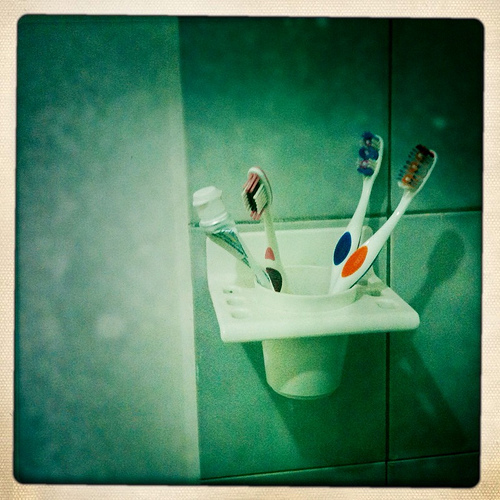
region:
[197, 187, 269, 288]
The tube of toothpaste.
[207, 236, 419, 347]
The toothbrush holder.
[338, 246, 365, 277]
The orange oval on the toothbrush.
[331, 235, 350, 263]
The blue oval on the toothbrush.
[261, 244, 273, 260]
The pink design on the toothbrush.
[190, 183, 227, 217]
The cap of the toothpaste.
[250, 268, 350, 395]
The cup the toothbrushes and toothpaste are in.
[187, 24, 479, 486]
The tile wall the toothbrush holder is mounted to.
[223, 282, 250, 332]
The holes on the left of the cup.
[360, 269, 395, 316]
The holes to the right of the cup.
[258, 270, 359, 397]
white plastic cup in toothbrush holder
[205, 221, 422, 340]
ceramic toothbrush holder on wall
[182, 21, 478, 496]
green tile on the wall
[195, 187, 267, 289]
a partial tube of toothpast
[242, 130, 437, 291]
three toothbrushes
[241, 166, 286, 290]
the toothbrush with pink and green bristles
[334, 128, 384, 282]
the toothbrush with blue handle and blue bristles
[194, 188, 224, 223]
white cap on toothpaste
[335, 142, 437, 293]
toothbrush with orange on handle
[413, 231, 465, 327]
shadow of a toothbrush on the tile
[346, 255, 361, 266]
orange color on toothbrush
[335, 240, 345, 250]
blue color on toothbrush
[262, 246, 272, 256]
pink color on toothbrush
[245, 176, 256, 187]
pink bristles on top toothbrush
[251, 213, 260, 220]
pink bristles on bottom toothbrush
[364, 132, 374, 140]
blue bristles on top toothbrush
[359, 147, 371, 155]
blue bristles on middle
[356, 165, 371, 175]
blue bristles on bottom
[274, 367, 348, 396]
white cup in cup holder on wall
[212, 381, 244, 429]
teal green tile on wall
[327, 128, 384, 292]
blue and white toothbrush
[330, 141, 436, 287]
orange, blue and white toothbrush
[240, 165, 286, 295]
pink, white and black toothbrush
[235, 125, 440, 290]
three toothbrushes in white toothbrush holder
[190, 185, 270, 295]
toothpaste in white toothbrush holder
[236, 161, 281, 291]
pink, black and white toothbrush beside toothpaste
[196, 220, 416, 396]
white toothbrush holder hanging on wall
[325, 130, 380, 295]
white and blue toothbrush in white toothbrush holder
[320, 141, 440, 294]
orange, white and blue toothbrush in white toothbrush holder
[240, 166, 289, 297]
pink, black and white toothbrush in white toothbrush holder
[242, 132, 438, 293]
Three toothbrushes in a holder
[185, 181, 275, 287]
Almost empty tube of toothpaste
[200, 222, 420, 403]
White wall mounted toothbrush holder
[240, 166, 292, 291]
White toothbrush with green and pink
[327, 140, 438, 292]
White toothbrush with orange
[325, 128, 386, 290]
White toothbrush with blue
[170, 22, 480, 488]
Green tiled bathroom wall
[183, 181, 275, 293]
Silver tube with a white cap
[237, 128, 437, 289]
Three manual toothbrushes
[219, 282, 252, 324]
Three holders for toothbrushes